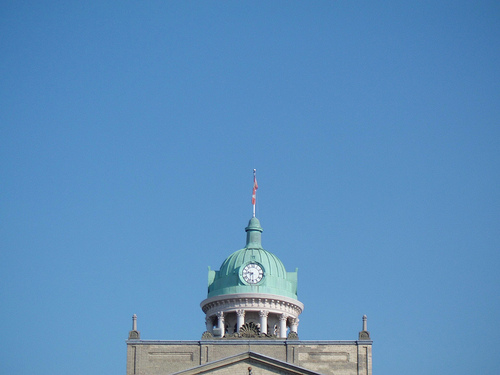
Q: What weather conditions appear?
A: It is clear.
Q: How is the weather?
A: It is clear.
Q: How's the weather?
A: It is clear.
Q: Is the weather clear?
A: Yes, it is clear.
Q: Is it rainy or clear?
A: It is clear.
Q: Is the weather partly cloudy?
A: No, it is clear.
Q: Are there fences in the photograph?
A: No, there are no fences.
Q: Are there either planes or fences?
A: No, there are no fences or planes.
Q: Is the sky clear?
A: Yes, the sky is clear.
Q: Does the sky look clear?
A: Yes, the sky is clear.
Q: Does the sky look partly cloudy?
A: No, the sky is clear.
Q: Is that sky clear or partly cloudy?
A: The sky is clear.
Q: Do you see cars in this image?
A: No, there are no cars.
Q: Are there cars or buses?
A: No, there are no cars or buses.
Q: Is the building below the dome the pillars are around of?
A: Yes, the building is below the dome.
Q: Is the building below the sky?
A: Yes, the building is below the sky.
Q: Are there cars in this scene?
A: No, there are no cars.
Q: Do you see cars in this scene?
A: No, there are no cars.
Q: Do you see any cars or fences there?
A: No, there are no cars or fences.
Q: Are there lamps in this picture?
A: No, there are no lamps.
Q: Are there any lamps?
A: No, there are no lamps.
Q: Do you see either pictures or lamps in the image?
A: No, there are no lamps or pictures.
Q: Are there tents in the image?
A: No, there are no tents.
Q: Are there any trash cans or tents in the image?
A: No, there are no tents or trash cans.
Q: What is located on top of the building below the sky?
A: The dome is on top of the building.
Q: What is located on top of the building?
A: The dome is on top of the building.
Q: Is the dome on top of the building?
A: Yes, the dome is on top of the building.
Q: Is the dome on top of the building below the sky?
A: Yes, the dome is on top of the building.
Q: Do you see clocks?
A: Yes, there is a clock.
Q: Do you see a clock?
A: Yes, there is a clock.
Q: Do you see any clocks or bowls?
A: Yes, there is a clock.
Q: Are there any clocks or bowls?
A: Yes, there is a clock.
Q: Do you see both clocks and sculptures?
A: No, there is a clock but no sculptures.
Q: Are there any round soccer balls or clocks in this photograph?
A: Yes, there is a round clock.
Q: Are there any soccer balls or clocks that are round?
A: Yes, the clock is round.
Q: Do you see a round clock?
A: Yes, there is a round clock.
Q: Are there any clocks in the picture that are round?
A: Yes, there is a clock that is round.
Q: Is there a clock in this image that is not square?
A: Yes, there is a round clock.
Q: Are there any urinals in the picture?
A: No, there are no urinals.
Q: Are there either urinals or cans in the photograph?
A: No, there are no urinals or cans.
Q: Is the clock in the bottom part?
A: Yes, the clock is in the bottom of the image.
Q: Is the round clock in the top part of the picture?
A: No, the clock is in the bottom of the image.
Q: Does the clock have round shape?
A: Yes, the clock is round.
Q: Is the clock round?
A: Yes, the clock is round.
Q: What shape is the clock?
A: The clock is round.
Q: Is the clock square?
A: No, the clock is round.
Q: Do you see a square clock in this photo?
A: No, there is a clock but it is round.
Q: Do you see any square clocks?
A: No, there is a clock but it is round.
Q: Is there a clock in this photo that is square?
A: No, there is a clock but it is round.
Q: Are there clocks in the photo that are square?
A: No, there is a clock but it is round.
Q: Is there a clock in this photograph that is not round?
A: No, there is a clock but it is round.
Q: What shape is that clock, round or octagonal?
A: The clock is round.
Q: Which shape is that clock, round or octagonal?
A: The clock is round.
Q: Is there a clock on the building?
A: Yes, there is a clock on the building.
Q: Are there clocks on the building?
A: Yes, there is a clock on the building.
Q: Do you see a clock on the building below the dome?
A: Yes, there is a clock on the building.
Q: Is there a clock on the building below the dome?
A: Yes, there is a clock on the building.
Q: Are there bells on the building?
A: No, there is a clock on the building.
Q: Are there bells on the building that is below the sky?
A: No, there is a clock on the building.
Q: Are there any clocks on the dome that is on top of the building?
A: Yes, there is a clock on the dome.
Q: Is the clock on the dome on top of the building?
A: Yes, the clock is on the dome.